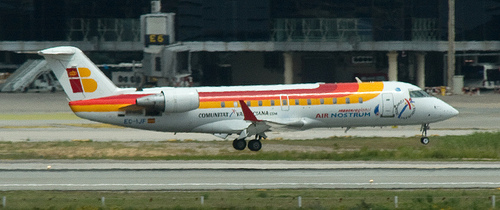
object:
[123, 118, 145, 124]
ec-uf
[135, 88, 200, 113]
engine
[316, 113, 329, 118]
air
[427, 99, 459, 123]
nose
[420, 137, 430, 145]
wheel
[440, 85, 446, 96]
can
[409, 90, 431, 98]
window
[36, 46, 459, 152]
plane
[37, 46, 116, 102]
tail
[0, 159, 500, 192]
runway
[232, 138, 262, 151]
landing gear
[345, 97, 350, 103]
window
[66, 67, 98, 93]
symbol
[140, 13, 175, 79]
sign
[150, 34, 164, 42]
e6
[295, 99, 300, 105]
window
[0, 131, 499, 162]
grass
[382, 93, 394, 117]
door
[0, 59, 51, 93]
ramp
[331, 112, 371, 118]
writing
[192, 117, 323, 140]
wing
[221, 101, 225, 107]
window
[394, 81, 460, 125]
front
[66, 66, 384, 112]
colors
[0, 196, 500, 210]
fence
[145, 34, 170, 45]
letters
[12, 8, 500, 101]
distance